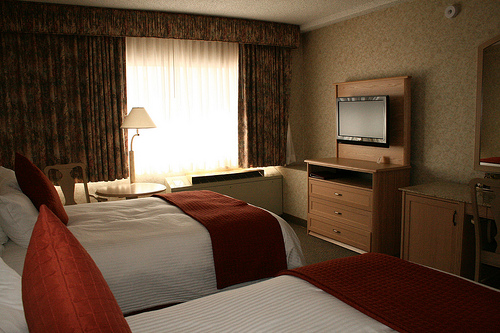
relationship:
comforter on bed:
[98, 196, 190, 276] [0, 161, 305, 311]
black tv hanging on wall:
[334, 94, 393, 148] [334, 74, 409, 160]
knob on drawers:
[334, 190, 340, 200] [300, 171, 381, 252]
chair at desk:
[468, 173, 499, 279] [413, 187, 499, 272]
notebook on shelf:
[308, 174, 331, 179] [307, 164, 371, 189]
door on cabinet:
[396, 190, 468, 277] [407, 192, 487, 271]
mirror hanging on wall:
[473, 33, 499, 175] [289, 1, 496, 188]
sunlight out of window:
[128, 61, 238, 177] [121, 33, 244, 180]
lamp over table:
[120, 105, 155, 186] [95, 180, 166, 197]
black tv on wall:
[334, 94, 393, 148] [310, 6, 485, 186]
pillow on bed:
[20, 206, 132, 331] [2, 183, 302, 313]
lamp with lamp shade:
[120, 106, 157, 183] [116, 104, 158, 187]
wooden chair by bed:
[43, 158, 93, 210] [2, 165, 314, 331]